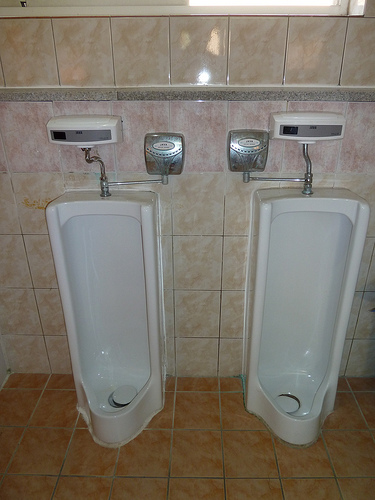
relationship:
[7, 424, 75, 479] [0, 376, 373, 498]
tile on floor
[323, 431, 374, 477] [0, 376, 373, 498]
tile on floor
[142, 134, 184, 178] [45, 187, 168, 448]
panel for urinal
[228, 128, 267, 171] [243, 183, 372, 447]
panel for urinal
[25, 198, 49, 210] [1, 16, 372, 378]
corrosion on wall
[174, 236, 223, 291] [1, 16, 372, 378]
tile on wall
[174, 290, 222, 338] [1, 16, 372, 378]
tile on wall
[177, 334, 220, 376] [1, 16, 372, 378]
tile on wall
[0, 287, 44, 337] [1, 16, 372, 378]
tile on wall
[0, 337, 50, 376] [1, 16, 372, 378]
tile on wall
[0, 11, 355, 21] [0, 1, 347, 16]
frame of window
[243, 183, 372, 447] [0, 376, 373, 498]
urinal attached to floor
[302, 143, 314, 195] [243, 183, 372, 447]
pipe on urinal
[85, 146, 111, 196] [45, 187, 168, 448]
pipe on urinal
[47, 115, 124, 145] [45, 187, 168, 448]
tank above urinal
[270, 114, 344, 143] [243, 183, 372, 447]
tank above urinal